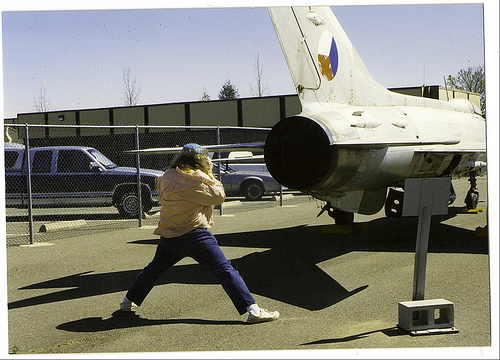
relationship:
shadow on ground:
[6, 205, 489, 345] [254, 265, 382, 351]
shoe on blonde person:
[247, 308, 279, 323] [120, 143, 279, 323]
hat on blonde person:
[181, 140, 210, 156] [120, 143, 279, 323]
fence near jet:
[4, 121, 282, 248] [264, 6, 486, 234]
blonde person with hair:
[120, 143, 279, 323] [166, 147, 223, 169]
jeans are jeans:
[126, 228, 257, 315] [113, 226, 258, 321]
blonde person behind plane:
[120, 143, 279, 323] [261, 6, 491, 227]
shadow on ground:
[6, 205, 489, 345] [2, 196, 495, 353]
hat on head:
[182, 143, 202, 153] [163, 127, 217, 181]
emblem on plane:
[317, 31, 339, 82] [261, 6, 491, 227]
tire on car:
[109, 182, 151, 218] [13, 152, 168, 215]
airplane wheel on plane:
[464, 192, 478, 209] [251, 11, 488, 358]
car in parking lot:
[18, 124, 260, 198] [1, 91, 296, 272]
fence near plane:
[4, 121, 282, 248] [239, 32, 491, 244]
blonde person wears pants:
[120, 143, 279, 323] [125, 221, 259, 317]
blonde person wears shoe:
[120, 143, 279, 323] [247, 308, 279, 323]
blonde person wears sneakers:
[120, 143, 279, 323] [118, 297, 137, 313]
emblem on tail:
[292, 36, 359, 93] [259, 16, 426, 237]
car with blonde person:
[2, 142, 298, 216] [120, 143, 279, 323]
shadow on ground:
[253, 201, 388, 344] [9, 175, 478, 348]